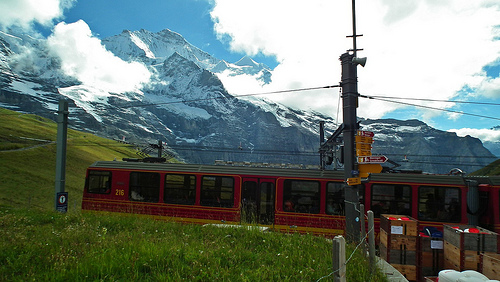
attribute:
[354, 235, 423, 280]
curb — concrete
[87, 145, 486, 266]
train — red, gray, parked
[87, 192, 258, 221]
line — yellow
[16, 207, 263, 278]
grass — green, high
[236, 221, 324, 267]
flowers — small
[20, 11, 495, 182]
mountains — large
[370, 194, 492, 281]
boxes — wooden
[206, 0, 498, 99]
cloud — large, white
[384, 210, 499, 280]
crates — brown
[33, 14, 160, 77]
clouds — white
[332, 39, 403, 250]
pole — tall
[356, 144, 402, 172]
sign — red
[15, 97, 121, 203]
hills — grassy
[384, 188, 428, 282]
box — brown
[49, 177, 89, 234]
sign — black